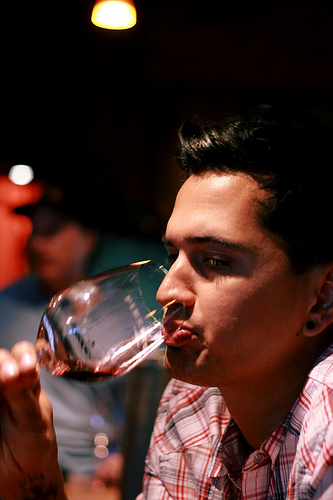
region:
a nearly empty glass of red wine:
[25, 243, 191, 395]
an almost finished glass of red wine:
[30, 253, 192, 394]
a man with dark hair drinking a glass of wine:
[8, 112, 325, 486]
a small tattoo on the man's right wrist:
[12, 466, 66, 499]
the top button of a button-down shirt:
[247, 446, 269, 467]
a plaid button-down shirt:
[128, 347, 330, 496]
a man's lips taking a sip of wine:
[153, 313, 201, 347]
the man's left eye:
[196, 250, 238, 274]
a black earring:
[300, 316, 322, 337]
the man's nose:
[152, 246, 199, 309]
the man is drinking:
[47, 246, 222, 374]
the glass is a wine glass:
[40, 321, 165, 388]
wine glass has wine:
[48, 331, 191, 400]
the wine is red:
[48, 320, 117, 377]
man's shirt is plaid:
[164, 393, 235, 487]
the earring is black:
[299, 299, 331, 344]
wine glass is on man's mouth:
[94, 254, 211, 373]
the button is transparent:
[252, 450, 273, 473]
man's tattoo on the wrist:
[13, 460, 56, 498]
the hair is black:
[190, 155, 331, 210]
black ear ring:
[303, 318, 327, 346]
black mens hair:
[223, 142, 329, 238]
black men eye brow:
[186, 240, 264, 255]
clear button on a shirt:
[252, 448, 281, 482]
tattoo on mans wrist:
[14, 475, 79, 498]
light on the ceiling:
[71, 6, 158, 37]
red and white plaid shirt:
[165, 410, 212, 484]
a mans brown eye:
[196, 245, 247, 280]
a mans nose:
[159, 251, 200, 319]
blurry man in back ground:
[18, 184, 97, 290]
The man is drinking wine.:
[30, 288, 211, 394]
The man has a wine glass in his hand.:
[26, 282, 187, 392]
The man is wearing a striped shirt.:
[139, 389, 331, 489]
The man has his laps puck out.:
[159, 310, 200, 352]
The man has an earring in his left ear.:
[286, 315, 331, 355]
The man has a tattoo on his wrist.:
[26, 470, 79, 499]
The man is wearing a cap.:
[30, 173, 125, 239]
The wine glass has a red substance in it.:
[55, 294, 143, 386]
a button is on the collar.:
[243, 442, 285, 470]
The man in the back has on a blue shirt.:
[15, 282, 133, 438]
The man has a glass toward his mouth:
[33, 283, 226, 381]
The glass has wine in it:
[39, 284, 149, 374]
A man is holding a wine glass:
[17, 255, 212, 422]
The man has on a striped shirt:
[153, 377, 325, 494]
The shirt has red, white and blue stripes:
[157, 379, 331, 498]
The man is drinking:
[67, 219, 330, 387]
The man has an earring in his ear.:
[282, 311, 327, 345]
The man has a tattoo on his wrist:
[16, 465, 84, 499]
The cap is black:
[23, 176, 119, 233]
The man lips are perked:
[151, 316, 237, 367]